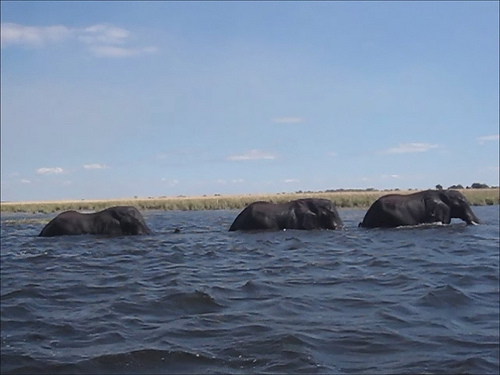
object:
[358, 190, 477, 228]
elephant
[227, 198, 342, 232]
elephant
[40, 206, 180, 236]
elephant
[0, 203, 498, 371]
water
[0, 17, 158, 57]
clouds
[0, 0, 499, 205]
sky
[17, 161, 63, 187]
clouds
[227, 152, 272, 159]
clouds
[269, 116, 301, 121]
clouds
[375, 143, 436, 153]
clouds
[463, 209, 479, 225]
trunk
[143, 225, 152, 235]
trunk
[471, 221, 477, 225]
tusk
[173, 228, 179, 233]
end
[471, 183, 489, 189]
trees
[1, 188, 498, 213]
land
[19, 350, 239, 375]
waves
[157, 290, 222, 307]
waves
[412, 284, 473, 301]
waves